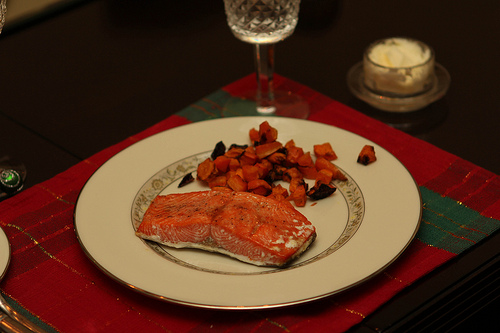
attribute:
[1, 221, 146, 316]
stripe — gold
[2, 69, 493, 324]
placemat — red, green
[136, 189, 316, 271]
salmon — orange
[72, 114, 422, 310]
rim — gold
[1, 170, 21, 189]
mark — green